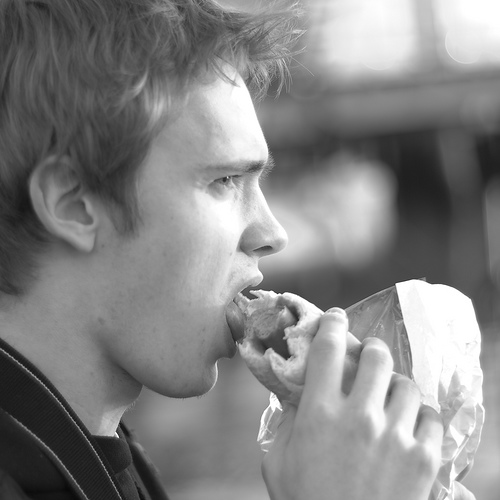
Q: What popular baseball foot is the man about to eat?
A: Hotdog.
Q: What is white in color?
A: The trim of the strap.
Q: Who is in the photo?
A: A man.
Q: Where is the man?
A: Outside somewhere.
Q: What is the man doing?
A: Eating.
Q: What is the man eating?
A: Hot dog.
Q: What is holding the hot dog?
A: Hand.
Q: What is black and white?
A: The whole photo.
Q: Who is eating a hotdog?
A: A man.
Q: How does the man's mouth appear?
A: Opened.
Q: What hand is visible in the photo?
A: Right hand.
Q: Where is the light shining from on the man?
A: Sun.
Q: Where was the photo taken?
A: In the outdoors.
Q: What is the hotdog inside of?
A: A bun.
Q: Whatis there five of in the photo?
A: FIngers.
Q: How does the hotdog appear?
A: Bitten.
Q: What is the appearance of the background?
A: Blurry.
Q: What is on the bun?
A: A wrapper.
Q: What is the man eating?
A: A hot dog.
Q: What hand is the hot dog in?
A: The right hand.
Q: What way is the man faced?
A: To the right.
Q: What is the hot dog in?
A: A bun.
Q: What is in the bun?
A: A hot dog.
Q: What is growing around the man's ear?
A: The man's hair.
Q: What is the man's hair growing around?
A: The man's ear.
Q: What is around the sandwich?
A: Paper wrapper.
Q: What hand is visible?
A: The right hand.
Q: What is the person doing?
A: Eating.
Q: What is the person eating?
A: Hotdog.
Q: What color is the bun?
A: White.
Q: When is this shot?
A: Daytime.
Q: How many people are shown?
A: 1.